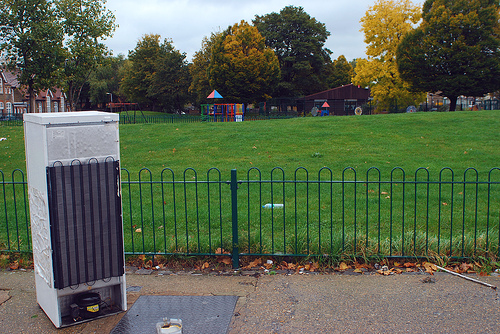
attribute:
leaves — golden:
[348, 0, 429, 114]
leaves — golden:
[394, 0, 499, 114]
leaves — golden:
[209, 20, 278, 105]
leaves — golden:
[111, 30, 193, 115]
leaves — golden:
[323, 53, 353, 90]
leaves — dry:
[144, 240, 474, 290]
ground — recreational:
[368, 160, 424, 211]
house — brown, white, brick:
[5, 59, 109, 152]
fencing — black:
[1, 160, 496, 273]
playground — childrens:
[189, 88, 383, 127]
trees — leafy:
[1, 0, 499, 115]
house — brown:
[299, 77, 385, 135]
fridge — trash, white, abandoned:
[23, 107, 131, 319]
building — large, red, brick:
[4, 62, 72, 120]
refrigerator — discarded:
[20, 106, 125, 326]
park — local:
[6, 54, 497, 263]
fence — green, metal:
[9, 173, 494, 263]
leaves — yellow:
[360, 57, 390, 83]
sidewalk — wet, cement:
[271, 279, 497, 309]